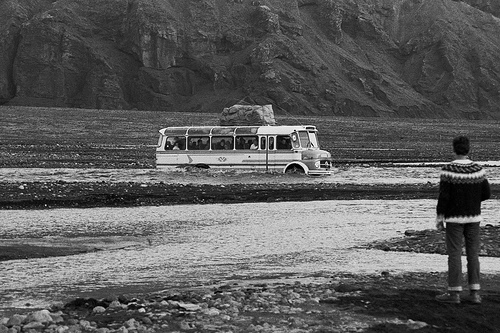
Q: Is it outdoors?
A: Yes, it is outdoors.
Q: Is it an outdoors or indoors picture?
A: It is outdoors.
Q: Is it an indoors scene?
A: No, it is outdoors.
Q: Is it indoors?
A: No, it is outdoors.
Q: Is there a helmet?
A: No, there are no helmets.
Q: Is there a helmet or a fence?
A: No, there are no helmets or fences.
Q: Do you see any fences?
A: No, there are no fences.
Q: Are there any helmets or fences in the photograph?
A: No, there are no fences or helmets.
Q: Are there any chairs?
A: No, there are no chairs.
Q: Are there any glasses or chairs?
A: No, there are no chairs or glasses.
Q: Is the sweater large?
A: Yes, the sweater is large.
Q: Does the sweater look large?
A: Yes, the sweater is large.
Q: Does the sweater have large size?
A: Yes, the sweater is large.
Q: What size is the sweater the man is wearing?
A: The sweater is large.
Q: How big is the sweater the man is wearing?
A: The sweater is large.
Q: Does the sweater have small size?
A: No, the sweater is large.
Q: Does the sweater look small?
A: No, the sweater is large.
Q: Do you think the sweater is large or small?
A: The sweater is large.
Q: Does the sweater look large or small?
A: The sweater is large.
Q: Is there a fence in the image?
A: No, there are no fences.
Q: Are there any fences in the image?
A: No, there are no fences.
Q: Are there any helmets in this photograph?
A: No, there are no helmets.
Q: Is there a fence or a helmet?
A: No, there are no helmets or fences.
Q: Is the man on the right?
A: Yes, the man is on the right of the image.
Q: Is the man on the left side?
A: No, the man is on the right of the image.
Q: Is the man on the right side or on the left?
A: The man is on the right of the image.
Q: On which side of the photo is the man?
A: The man is on the right of the image.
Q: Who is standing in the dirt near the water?
A: The man is standing in the dirt.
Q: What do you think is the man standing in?
A: The man is standing in the dirt.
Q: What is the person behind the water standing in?
A: The man is standing in the dirt.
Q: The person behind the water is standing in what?
A: The man is standing in the dirt.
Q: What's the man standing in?
A: The man is standing in the dirt.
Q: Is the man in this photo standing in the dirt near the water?
A: Yes, the man is standing in the dirt.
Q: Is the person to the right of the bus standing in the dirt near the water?
A: Yes, the man is standing in the dirt.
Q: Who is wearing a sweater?
A: The man is wearing a sweater.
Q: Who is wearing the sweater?
A: The man is wearing a sweater.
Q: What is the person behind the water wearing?
A: The man is wearing a sweater.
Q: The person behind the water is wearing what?
A: The man is wearing a sweater.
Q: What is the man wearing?
A: The man is wearing a sweater.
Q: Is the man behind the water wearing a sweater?
A: Yes, the man is wearing a sweater.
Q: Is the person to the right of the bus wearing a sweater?
A: Yes, the man is wearing a sweater.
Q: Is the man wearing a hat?
A: No, the man is wearing a sweater.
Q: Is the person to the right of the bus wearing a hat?
A: No, the man is wearing a sweater.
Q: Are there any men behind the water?
A: Yes, there is a man behind the water.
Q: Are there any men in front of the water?
A: No, the man is behind the water.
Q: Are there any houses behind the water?
A: No, there is a man behind the water.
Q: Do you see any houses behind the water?
A: No, there is a man behind the water.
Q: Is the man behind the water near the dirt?
A: Yes, the man is behind the water.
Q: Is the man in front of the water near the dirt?
A: No, the man is behind the water.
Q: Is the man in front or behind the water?
A: The man is behind the water.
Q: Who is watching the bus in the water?
A: The man is watching the bus.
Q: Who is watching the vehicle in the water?
A: The man is watching the bus.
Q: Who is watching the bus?
A: The man is watching the bus.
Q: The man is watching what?
A: The man is watching the bus.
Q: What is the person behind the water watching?
A: The man is watching the bus.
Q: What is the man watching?
A: The man is watching the bus.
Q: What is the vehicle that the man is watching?
A: The vehicle is a bus.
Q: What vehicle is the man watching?
A: The man is watching the bus.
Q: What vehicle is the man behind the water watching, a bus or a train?
A: The man is watching a bus.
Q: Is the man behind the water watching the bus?
A: Yes, the man is watching the bus.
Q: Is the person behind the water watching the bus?
A: Yes, the man is watching the bus.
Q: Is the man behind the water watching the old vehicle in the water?
A: Yes, the man is watching the bus.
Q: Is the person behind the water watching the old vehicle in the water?
A: Yes, the man is watching the bus.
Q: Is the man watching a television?
A: No, the man is watching the bus.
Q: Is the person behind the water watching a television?
A: No, the man is watching the bus.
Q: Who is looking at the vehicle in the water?
A: The man is looking at the bus.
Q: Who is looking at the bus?
A: The man is looking at the bus.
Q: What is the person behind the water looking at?
A: The man is looking at the bus.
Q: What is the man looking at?
A: The man is looking at the bus.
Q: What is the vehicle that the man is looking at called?
A: The vehicle is a bus.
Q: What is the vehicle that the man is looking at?
A: The vehicle is a bus.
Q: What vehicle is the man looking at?
A: The man is looking at the bus.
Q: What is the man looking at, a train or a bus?
A: The man is looking at a bus.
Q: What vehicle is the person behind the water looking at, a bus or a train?
A: The man is looking at a bus.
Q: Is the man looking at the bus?
A: Yes, the man is looking at the bus.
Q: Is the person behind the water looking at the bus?
A: Yes, the man is looking at the bus.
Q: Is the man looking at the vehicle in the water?
A: Yes, the man is looking at the bus.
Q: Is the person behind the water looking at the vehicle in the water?
A: Yes, the man is looking at the bus.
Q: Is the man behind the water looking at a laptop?
A: No, the man is looking at the bus.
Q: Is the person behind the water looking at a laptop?
A: No, the man is looking at the bus.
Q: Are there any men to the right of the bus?
A: Yes, there is a man to the right of the bus.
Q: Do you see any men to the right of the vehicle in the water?
A: Yes, there is a man to the right of the bus.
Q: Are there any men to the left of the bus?
A: No, the man is to the right of the bus.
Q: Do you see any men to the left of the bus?
A: No, the man is to the right of the bus.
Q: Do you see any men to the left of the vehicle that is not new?
A: No, the man is to the right of the bus.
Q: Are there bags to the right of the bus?
A: No, there is a man to the right of the bus.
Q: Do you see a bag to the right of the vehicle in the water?
A: No, there is a man to the right of the bus.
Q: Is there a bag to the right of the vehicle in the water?
A: No, there is a man to the right of the bus.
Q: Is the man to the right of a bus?
A: Yes, the man is to the right of a bus.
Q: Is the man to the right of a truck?
A: No, the man is to the right of a bus.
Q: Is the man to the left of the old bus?
A: No, the man is to the right of the bus.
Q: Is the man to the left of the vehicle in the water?
A: No, the man is to the right of the bus.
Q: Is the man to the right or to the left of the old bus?
A: The man is to the right of the bus.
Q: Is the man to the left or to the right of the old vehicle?
A: The man is to the right of the bus.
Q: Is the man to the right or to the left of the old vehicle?
A: The man is to the right of the bus.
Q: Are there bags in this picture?
A: No, there are no bags.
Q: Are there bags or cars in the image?
A: No, there are no bags or cars.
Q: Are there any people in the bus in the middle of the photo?
A: Yes, there are people in the bus.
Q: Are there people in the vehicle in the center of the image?
A: Yes, there are people in the bus.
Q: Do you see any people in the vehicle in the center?
A: Yes, there are people in the bus.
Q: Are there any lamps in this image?
A: No, there are no lamps.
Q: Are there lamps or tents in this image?
A: No, there are no lamps or tents.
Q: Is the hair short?
A: Yes, the hair is short.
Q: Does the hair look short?
A: Yes, the hair is short.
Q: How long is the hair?
A: The hair is short.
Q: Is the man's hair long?
A: No, the hair is short.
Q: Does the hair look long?
A: No, the hair is short.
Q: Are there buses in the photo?
A: Yes, there is a bus.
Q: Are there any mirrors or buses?
A: Yes, there is a bus.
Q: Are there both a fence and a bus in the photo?
A: No, there is a bus but no fences.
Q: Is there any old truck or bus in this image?
A: Yes, there is an old bus.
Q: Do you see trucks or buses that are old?
A: Yes, the bus is old.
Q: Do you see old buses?
A: Yes, there is an old bus.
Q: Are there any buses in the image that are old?
A: Yes, there is a bus that is old.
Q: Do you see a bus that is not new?
A: Yes, there is a old bus.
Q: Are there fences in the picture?
A: No, there are no fences.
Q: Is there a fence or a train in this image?
A: No, there are no fences or trains.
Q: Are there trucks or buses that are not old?
A: No, there is a bus but it is old.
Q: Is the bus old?
A: Yes, the bus is old.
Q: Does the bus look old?
A: Yes, the bus is old.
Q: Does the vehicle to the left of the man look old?
A: Yes, the bus is old.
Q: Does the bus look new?
A: No, the bus is old.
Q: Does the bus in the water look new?
A: No, the bus is old.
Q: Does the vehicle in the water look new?
A: No, the bus is old.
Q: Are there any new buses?
A: No, there is a bus but it is old.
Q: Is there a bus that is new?
A: No, there is a bus but it is old.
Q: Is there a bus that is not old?
A: No, there is a bus but it is old.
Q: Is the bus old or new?
A: The bus is old.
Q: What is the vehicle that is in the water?
A: The vehicle is a bus.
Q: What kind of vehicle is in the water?
A: The vehicle is a bus.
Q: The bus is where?
A: The bus is in the water.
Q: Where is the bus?
A: The bus is in the water.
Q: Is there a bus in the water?
A: Yes, there is a bus in the water.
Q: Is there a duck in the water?
A: No, there is a bus in the water.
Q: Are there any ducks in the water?
A: No, there is a bus in the water.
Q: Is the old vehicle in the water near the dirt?
A: Yes, the bus is in the water.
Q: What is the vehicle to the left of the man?
A: The vehicle is a bus.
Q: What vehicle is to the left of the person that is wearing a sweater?
A: The vehicle is a bus.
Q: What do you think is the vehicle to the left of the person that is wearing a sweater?
A: The vehicle is a bus.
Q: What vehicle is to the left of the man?
A: The vehicle is a bus.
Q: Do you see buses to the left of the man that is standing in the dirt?
A: Yes, there is a bus to the left of the man.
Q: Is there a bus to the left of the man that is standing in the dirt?
A: Yes, there is a bus to the left of the man.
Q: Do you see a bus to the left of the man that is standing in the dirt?
A: Yes, there is a bus to the left of the man.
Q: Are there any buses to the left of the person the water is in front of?
A: Yes, there is a bus to the left of the man.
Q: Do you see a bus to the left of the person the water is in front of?
A: Yes, there is a bus to the left of the man.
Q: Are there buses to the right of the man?
A: No, the bus is to the left of the man.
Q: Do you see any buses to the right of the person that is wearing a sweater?
A: No, the bus is to the left of the man.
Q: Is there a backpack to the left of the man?
A: No, there is a bus to the left of the man.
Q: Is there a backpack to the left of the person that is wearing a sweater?
A: No, there is a bus to the left of the man.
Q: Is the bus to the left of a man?
A: Yes, the bus is to the left of a man.